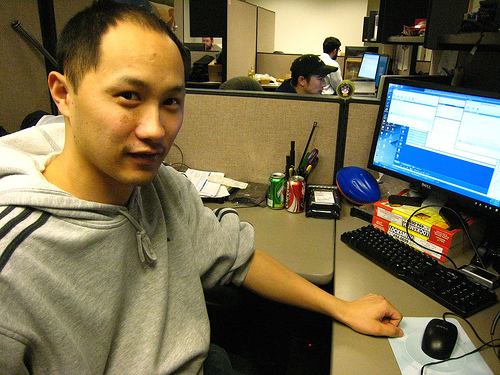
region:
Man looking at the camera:
[31, 1, 207, 226]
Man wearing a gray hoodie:
[1, 0, 412, 374]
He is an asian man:
[26, 0, 207, 213]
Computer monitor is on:
[362, 61, 499, 220]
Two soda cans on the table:
[253, 110, 335, 239]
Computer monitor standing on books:
[360, 55, 499, 309]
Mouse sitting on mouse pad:
[368, 288, 498, 374]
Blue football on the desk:
[330, 157, 387, 219]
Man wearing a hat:
[277, 50, 348, 101]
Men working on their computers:
[279, 23, 397, 109]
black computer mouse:
[408, 313, 470, 365]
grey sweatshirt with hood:
[2, 116, 260, 373]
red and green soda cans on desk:
[260, 166, 310, 218]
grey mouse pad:
[385, 305, 493, 373]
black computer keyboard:
[337, 213, 497, 328]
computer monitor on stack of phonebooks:
[364, 73, 498, 218]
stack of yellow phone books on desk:
[371, 184, 483, 264]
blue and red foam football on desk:
[324, 156, 382, 207]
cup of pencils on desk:
[273, 115, 320, 181]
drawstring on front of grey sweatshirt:
[112, 187, 170, 273]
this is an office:
[288, 196, 391, 314]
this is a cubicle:
[215, 210, 337, 322]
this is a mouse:
[370, 288, 452, 325]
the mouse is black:
[429, 303, 443, 368]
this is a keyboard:
[277, 237, 468, 260]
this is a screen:
[366, 145, 449, 247]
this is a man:
[96, 157, 178, 304]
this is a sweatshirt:
[7, 213, 103, 299]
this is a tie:
[132, 207, 172, 254]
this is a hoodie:
[22, 147, 65, 247]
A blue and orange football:
[335, 164, 381, 206]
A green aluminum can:
[265, 170, 285, 208]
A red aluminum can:
[285, 176, 304, 216]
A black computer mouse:
[419, 316, 459, 359]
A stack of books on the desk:
[372, 188, 477, 259]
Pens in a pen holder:
[283, 121, 321, 180]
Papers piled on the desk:
[183, 168, 248, 199]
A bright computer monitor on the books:
[368, 76, 498, 216]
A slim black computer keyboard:
[341, 223, 497, 315]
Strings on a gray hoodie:
[116, 196, 160, 266]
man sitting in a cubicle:
[6, 5, 498, 373]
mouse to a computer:
[397, 306, 462, 366]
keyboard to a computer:
[340, 208, 491, 318]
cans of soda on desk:
[259, 163, 317, 223]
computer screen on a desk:
[371, 74, 498, 214]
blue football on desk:
[337, 156, 390, 220]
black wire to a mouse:
[446, 303, 493, 368]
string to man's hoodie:
[116, 208, 172, 278]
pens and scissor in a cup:
[275, 137, 325, 170]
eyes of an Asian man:
[109, 69, 193, 124]